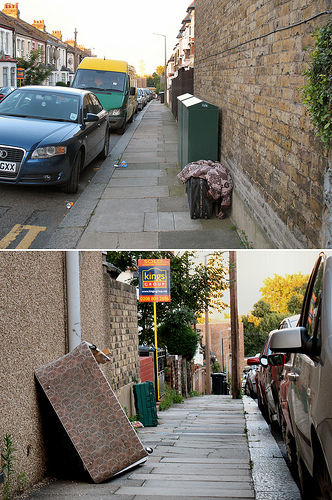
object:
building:
[194, 0, 332, 249]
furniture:
[33, 341, 154, 482]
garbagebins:
[212, 370, 230, 394]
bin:
[132, 379, 161, 429]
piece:
[35, 339, 150, 483]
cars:
[269, 247, 331, 500]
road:
[247, 387, 319, 499]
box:
[133, 378, 161, 429]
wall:
[0, 250, 108, 498]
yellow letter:
[156, 273, 159, 281]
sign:
[136, 253, 170, 303]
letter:
[144, 260, 149, 270]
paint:
[14, 221, 46, 249]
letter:
[159, 272, 165, 285]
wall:
[191, 0, 331, 247]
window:
[15, 38, 22, 57]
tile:
[111, 167, 166, 179]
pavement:
[43, 99, 249, 247]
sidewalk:
[61, 99, 249, 247]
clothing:
[176, 159, 249, 217]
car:
[1, 85, 111, 196]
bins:
[180, 96, 222, 178]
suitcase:
[185, 177, 216, 223]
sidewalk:
[23, 392, 301, 499]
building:
[0, 1, 70, 99]